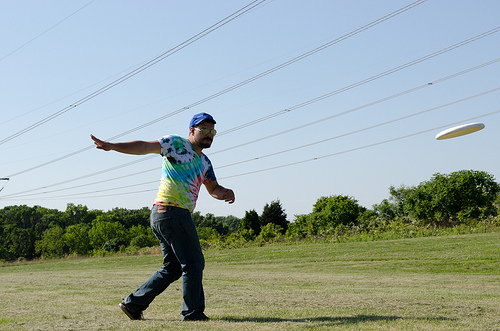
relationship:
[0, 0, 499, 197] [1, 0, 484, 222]
power lines in air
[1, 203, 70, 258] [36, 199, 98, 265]
tree by tree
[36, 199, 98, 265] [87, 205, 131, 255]
tree by tree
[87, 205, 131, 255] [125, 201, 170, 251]
tree by tree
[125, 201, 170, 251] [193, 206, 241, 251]
tree by tree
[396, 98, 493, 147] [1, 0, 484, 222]
frisbee in air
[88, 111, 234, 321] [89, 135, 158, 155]
man with arm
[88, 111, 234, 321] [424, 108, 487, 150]
man throws frisbee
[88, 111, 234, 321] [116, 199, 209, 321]
man wears jeans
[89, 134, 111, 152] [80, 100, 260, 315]
hand of person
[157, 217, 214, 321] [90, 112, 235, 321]
leg of person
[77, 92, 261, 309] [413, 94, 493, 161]
man just threw frisbee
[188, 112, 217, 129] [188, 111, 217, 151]
blue hat on head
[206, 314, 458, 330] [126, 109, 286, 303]
shadow of man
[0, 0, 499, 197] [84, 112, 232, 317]
power lines above man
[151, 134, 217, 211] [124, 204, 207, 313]
shirt and jeans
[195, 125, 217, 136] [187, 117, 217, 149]
glass worn on face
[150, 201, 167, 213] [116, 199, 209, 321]
brand tag on jeans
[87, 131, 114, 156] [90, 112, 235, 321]
hand on person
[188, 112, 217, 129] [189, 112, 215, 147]
blue hat on head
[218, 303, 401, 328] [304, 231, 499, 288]
shadow on grass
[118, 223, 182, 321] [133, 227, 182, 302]
leg of leg